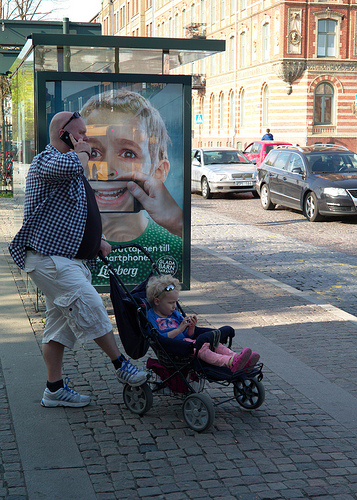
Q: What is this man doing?
A: Pushing a baby.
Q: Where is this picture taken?
A: A street.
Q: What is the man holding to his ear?
A: A phone.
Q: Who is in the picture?
A: A man and a baby.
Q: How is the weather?
A: Sunny.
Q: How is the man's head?
A: Bald.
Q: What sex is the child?
A: A girl.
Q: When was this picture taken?
A: Daytime.